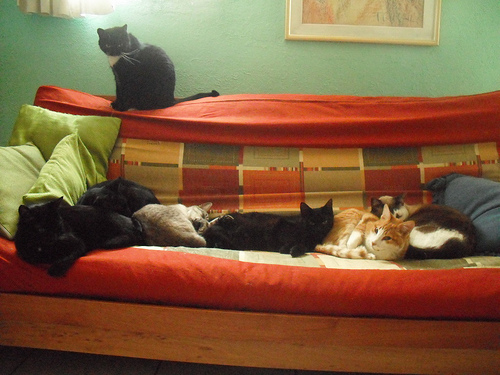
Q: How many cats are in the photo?
A: Seven.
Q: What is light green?
A: Wall.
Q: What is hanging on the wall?
A: Painting.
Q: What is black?
A: Four cats.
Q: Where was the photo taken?
A: In a living room.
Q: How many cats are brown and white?
A: One.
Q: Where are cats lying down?
A: On a couch.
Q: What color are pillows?
A: Green.